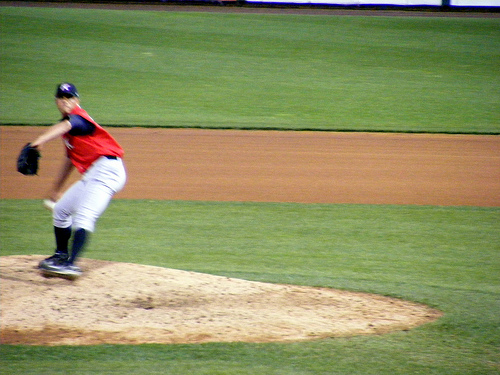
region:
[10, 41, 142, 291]
a man throwing a ball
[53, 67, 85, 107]
a man wearing a blue hat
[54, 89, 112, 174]
a man wearing a red and blue shirt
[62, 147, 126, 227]
a man wearing white pants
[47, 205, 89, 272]
a man wearing black socks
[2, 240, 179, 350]
the pitchers mound on a baseball field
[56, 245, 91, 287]
a man with one foot raised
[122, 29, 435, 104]
green grass on a baseball field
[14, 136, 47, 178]
a man wearing a baseball glove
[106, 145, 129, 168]
a man wearing a black belt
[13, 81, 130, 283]
Person throwing a baseball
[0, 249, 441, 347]
Pitching area on the baseball field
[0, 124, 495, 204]
Untouched sand area on the field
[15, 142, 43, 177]
Black mitts on the right person's hand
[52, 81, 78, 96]
Blue cap on the person's head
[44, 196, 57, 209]
Base ball on the person's left hand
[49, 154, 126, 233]
White pants worn by the person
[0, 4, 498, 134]
Green grassy area on the baseball field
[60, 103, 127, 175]
Red baseball uniform worn by person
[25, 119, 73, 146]
Right arm of the baseball player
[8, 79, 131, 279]
Baseball player about to pitch the ball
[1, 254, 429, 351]
Brown pitchers mound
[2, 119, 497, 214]
Dark brown dirt section of field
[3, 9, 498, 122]
Nicely maintained grassy area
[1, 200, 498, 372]
Green grassy area around pitchers mound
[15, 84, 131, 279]
Guy wearing the orange and white outfit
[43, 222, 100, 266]
Long black baseball socks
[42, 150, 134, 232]
White pants on baseball player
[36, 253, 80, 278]
Black and tan shoes on baseball player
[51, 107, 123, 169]
Blue and orange jersey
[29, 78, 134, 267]
man getting ready to pitch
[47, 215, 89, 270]
man in black socks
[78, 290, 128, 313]
man on pitchers mound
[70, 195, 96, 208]
man in white pants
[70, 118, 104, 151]
man wearing red jersey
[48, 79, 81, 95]
man wearing blue cap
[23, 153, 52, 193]
pitcher with black glove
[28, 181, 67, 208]
man with ball in hand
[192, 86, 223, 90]
green grass is striped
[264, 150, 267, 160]
orange sand by grass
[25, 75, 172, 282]
baseball player on field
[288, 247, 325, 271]
patch of green grass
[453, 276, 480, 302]
patch of green grass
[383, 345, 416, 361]
patch of green grass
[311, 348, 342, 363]
patch of green grass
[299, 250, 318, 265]
patch of green grass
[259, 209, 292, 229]
patch of green grass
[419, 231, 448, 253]
patch of green grass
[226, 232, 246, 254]
patch of green grass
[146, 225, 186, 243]
patch of green grass